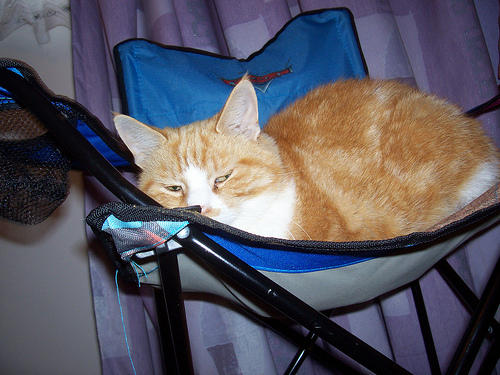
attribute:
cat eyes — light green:
[160, 176, 186, 196]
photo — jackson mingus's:
[6, 3, 484, 373]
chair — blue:
[107, 28, 468, 340]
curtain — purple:
[354, 5, 496, 125]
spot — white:
[178, 148, 212, 213]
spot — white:
[249, 188, 291, 221]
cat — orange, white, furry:
[103, 52, 489, 266]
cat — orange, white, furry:
[70, 76, 491, 199]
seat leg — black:
[146, 249, 201, 371]